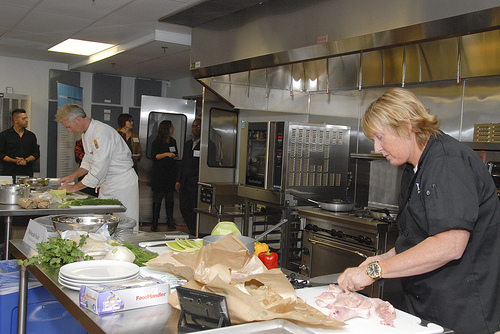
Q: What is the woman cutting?
A: Raw meat.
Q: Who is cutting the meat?
A: The woman.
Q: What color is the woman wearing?
A: Black.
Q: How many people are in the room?
A: Seven.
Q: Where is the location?
A: Kitchen.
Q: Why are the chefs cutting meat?
A: Preparing to cook.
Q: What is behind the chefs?
A: Stoves.